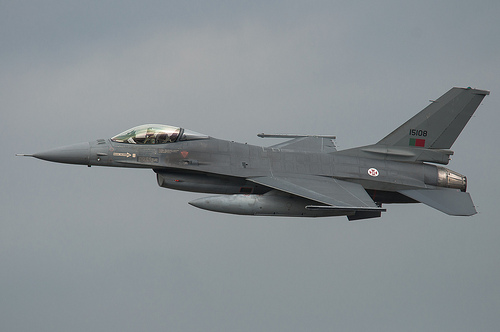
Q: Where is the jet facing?
A: Left.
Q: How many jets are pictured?
A: 1.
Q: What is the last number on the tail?
A: 8.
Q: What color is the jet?
A: Grey.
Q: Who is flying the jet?
A: The pilot.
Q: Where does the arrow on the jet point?
A: Right.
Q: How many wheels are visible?
A: Zero.